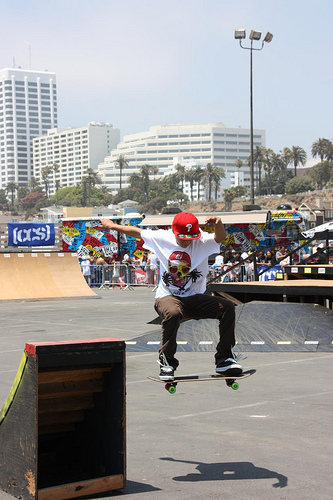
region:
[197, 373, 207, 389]
part of a board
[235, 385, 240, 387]
part of a wheel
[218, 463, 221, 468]
part of a shadow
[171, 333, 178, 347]
part of a knee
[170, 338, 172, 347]
part of a trouser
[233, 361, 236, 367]
part of a shoe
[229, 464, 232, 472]
part of a shadow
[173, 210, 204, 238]
a red baseball cap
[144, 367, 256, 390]
a long skateboard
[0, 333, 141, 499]
part of a skateboard ramp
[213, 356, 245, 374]
a boy's tennis shoe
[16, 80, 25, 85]
a window of a building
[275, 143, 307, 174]
a tall green tree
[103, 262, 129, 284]
a gray fence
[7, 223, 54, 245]
a large blue and white sign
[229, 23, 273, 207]
a tall light pole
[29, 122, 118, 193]
a white building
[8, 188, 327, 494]
Man in a park.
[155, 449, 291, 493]
A man's shadow in a park.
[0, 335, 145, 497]
A skateboard ramp.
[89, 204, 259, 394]
Man jumping on a skateboard.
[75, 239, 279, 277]
Spectators standing near a railing.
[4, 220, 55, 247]
Blue sign hung near a ramp.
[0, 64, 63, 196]
Tall building in the background.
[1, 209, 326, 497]
Man in a skateboard park.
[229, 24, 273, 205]
Outdoor light near a park.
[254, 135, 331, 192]
Palm trees in the distance.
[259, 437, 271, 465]
part of a surface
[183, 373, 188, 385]
part of a board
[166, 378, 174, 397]
part of a whee l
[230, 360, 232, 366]
part of a shoe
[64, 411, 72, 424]
part of a ramp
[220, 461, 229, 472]
part of a shadow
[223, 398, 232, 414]
edge of a court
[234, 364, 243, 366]
tip of a shoe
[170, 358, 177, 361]
part of a trouser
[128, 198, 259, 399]
Man on a skateboard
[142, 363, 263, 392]
White and black skateboard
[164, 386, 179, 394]
Green wheel on skareboard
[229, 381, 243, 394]
Green wheel on skateboard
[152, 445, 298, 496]
Shadow on the pavement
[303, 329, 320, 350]
White dash on the pavement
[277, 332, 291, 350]
White dash on the pavement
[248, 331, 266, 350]
White dash on the pavement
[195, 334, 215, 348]
White dash on the pavement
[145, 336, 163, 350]
White dash on the pavement